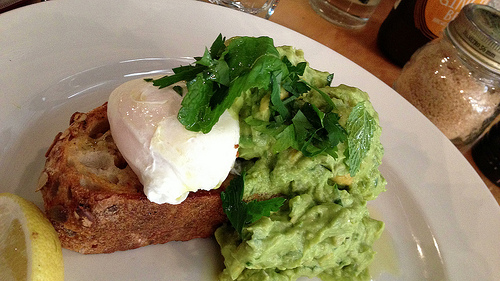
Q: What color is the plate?
A: White.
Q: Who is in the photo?
A: No one.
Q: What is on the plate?
A: Food.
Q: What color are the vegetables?
A: Green.